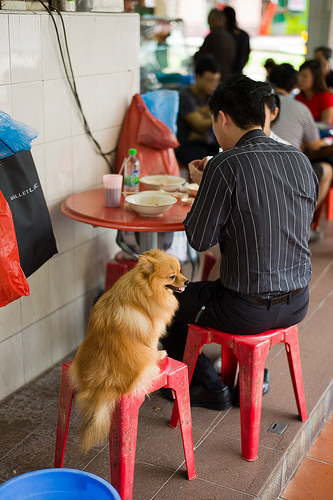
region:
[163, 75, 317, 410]
Man is sitting down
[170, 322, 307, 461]
The stool is red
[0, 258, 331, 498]
Floor tiles are brown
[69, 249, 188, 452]
Dog is sitting down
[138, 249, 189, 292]
Dog looking to the right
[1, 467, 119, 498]
The bucket is blue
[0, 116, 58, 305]
Bags hanging on the wall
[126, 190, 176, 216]
The bowl is white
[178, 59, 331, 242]
People are sitting down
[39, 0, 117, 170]
Black cord on wall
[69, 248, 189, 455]
dog sitting on red chair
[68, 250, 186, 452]
small brown dog sitting on chair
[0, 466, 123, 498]
blue container with water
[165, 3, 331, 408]
people sitting in restaurant eating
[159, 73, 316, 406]
couple with dog eating together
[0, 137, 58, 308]
black and orange bags hanging from wall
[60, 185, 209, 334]
small round table with food on it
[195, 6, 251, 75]
two people standing in the distance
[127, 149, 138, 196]
bottle of water on table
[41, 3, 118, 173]
black cords on wall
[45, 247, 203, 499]
a dog sitting on a red stool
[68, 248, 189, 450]
a brown dog sitting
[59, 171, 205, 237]
a round table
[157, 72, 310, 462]
a guy sitting on the red stool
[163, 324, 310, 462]
a red stool the guy is sitting on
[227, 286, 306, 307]
a black belt the guy is wearing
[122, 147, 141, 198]
a water bottle on the table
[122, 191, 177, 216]
a white bowl on the table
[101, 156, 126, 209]
a plastic cup with a straw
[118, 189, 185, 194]
a chopstick sitting on the bowl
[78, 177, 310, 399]
red table and chairs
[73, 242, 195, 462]
furry orange dog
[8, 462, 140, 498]
blue bucket on the ground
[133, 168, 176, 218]
two white bowls on the table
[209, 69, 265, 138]
man has black hair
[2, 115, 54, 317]
two bags are hanging on the wall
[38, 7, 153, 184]
black cables next to wall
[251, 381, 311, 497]
man on the edge of the curb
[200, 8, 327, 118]
people eating in the background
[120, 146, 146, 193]
bottle of water on the table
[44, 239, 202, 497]
dog sitting on red stool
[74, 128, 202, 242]
plastic bottle on table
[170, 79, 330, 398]
guy sitting on red stool at table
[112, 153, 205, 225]
bowls on the table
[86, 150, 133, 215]
cup with straw and drink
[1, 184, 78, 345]
orange plastic bag hanging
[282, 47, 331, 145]
person wearing red shirt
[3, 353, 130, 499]
blue object behind red stool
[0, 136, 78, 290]
black shopping bag with white writing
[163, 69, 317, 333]
guy wearing black and white stripe shirt